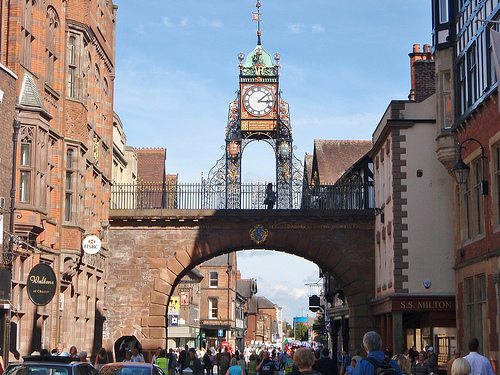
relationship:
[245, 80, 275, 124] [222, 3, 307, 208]
clock on tower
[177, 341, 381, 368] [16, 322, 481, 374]
people on street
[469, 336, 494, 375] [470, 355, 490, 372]
man with dress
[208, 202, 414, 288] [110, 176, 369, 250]
shadow on bridge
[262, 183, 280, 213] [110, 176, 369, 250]
girl on bridge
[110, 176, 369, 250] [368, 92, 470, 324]
bridge between buildings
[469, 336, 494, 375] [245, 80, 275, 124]
man watching clock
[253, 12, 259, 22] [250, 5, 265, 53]
flag on pole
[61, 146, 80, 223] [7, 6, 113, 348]
windows on building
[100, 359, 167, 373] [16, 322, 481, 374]
car on road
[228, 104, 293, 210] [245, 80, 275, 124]
archway under clock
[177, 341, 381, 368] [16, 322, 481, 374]
people in street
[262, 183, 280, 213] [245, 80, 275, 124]
person in front of clock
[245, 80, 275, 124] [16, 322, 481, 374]
clock above street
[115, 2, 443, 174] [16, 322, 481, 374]
sky above street